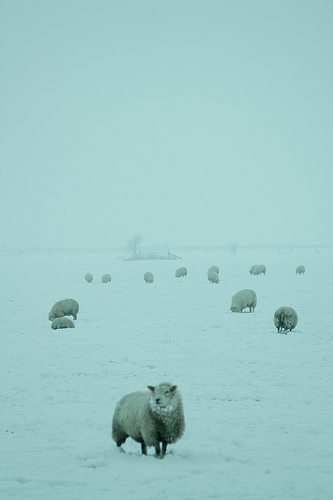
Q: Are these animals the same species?
A: Yes, all the animals are sheep.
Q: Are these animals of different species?
A: No, all the animals are sheep.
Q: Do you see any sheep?
A: Yes, there is a sheep.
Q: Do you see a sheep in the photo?
A: Yes, there is a sheep.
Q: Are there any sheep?
A: Yes, there is a sheep.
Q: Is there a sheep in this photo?
A: Yes, there is a sheep.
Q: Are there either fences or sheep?
A: Yes, there is a sheep.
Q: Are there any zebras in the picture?
A: No, there are no zebras.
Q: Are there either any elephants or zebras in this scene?
A: No, there are no zebras or elephants.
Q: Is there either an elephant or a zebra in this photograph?
A: No, there are no zebras or elephants.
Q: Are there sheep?
A: Yes, there is a sheep.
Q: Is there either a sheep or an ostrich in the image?
A: Yes, there is a sheep.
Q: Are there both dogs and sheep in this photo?
A: No, there is a sheep but no dogs.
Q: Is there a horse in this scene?
A: No, there are no horses.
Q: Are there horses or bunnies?
A: No, there are no horses or bunnies.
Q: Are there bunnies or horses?
A: No, there are no horses or bunnies.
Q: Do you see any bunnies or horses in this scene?
A: No, there are no horses or bunnies.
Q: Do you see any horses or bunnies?
A: No, there are no horses or bunnies.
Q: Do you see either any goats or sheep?
A: Yes, there is a sheep.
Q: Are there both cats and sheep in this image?
A: No, there is a sheep but no cats.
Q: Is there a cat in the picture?
A: No, there are no cats.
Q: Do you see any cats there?
A: No, there are no cats.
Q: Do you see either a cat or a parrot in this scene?
A: No, there are no cats or parrots.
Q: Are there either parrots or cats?
A: No, there are no cats or parrots.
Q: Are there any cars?
A: No, there are no cars.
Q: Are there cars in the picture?
A: No, there are no cars.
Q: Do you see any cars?
A: No, there are no cars.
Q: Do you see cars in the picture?
A: No, there are no cars.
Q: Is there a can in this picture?
A: No, there are no cans.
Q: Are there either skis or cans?
A: No, there are no cans or skis.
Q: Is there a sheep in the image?
A: Yes, there is a sheep.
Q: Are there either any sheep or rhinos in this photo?
A: Yes, there is a sheep.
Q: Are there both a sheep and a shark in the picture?
A: No, there is a sheep but no sharks.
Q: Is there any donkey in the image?
A: No, there are no donkeys.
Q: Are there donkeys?
A: No, there are no donkeys.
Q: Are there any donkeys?
A: No, there are no donkeys.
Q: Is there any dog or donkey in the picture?
A: No, there are no donkeys or dogs.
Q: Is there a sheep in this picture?
A: Yes, there is a sheep.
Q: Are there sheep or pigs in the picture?
A: Yes, there is a sheep.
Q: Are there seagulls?
A: No, there are no seagulls.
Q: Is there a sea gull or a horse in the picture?
A: No, there are no seagulls or horses.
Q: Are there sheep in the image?
A: Yes, there is a sheep.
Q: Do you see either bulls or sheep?
A: Yes, there is a sheep.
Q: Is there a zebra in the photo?
A: No, there are no zebras.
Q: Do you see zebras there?
A: No, there are no zebras.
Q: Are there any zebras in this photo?
A: No, there are no zebras.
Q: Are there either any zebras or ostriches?
A: No, there are no zebras or ostriches.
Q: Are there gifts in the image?
A: No, there are no gifts.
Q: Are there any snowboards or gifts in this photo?
A: No, there are no gifts or snowboards.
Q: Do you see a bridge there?
A: Yes, there is a bridge.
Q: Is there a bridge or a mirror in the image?
A: Yes, there is a bridge.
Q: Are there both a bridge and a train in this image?
A: No, there is a bridge but no trains.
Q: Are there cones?
A: No, there are no cones.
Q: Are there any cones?
A: No, there are no cones.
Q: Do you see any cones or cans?
A: No, there are no cones or cans.